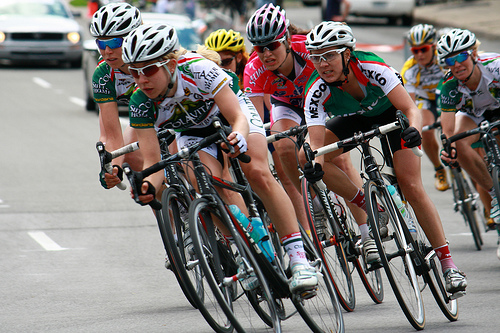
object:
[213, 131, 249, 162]
hand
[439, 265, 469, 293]
shoe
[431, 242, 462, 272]
sock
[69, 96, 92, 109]
markings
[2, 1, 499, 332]
road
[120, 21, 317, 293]
bike racer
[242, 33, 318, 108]
jersey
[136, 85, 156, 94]
lips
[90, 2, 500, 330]
bicycle races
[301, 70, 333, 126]
jersey sleeve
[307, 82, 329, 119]
mexico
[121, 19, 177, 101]
head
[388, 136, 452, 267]
leg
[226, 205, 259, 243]
bottles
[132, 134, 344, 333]
bicycle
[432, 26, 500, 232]
women cycling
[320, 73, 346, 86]
chin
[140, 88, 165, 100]
chin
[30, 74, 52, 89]
lines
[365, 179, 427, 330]
wheel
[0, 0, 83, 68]
car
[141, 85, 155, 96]
mouth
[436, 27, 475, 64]
white helmet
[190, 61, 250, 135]
arm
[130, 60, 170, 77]
sunglasses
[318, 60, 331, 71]
nose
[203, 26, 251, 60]
helmet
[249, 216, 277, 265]
water bottle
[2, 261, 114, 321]
asphalt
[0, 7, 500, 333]
lanes